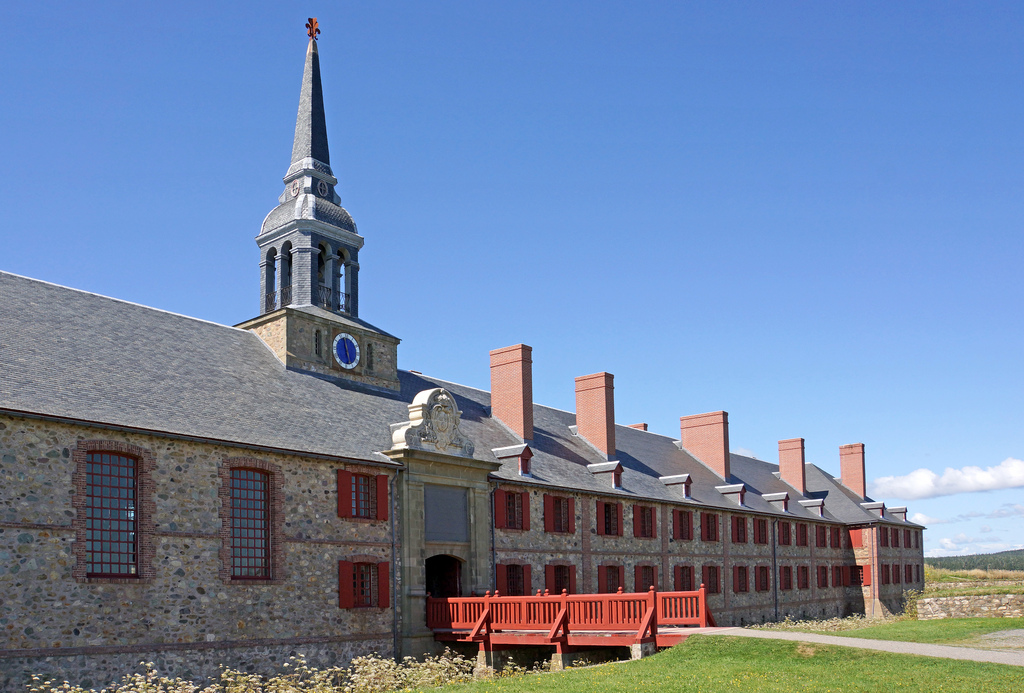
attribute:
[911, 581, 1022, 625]
wall — brick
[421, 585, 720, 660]
bridge — short, red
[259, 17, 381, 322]
tower — pointed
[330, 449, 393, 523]
window fram — red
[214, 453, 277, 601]
frame — stone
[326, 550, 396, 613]
frame — red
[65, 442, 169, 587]
frame — stone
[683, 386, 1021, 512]
clouds — white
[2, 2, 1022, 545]
sky — blue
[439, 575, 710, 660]
bridge — red, on the building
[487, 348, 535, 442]
chimney —  church's